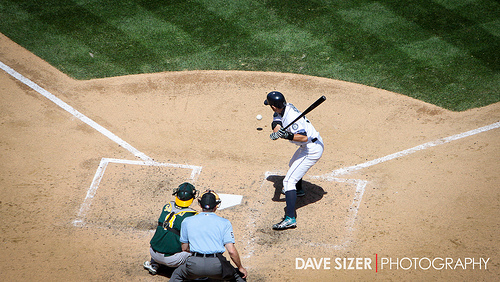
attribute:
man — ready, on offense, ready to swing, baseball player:
[264, 89, 327, 231]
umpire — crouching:
[168, 187, 249, 281]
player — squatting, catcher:
[143, 183, 199, 276]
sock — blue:
[285, 188, 299, 218]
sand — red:
[2, 30, 500, 281]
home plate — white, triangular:
[216, 193, 243, 213]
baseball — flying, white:
[256, 114, 263, 121]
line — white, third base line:
[0, 59, 152, 168]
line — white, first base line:
[319, 121, 499, 180]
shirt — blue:
[179, 210, 236, 254]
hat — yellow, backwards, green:
[175, 183, 195, 207]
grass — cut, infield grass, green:
[0, 0, 499, 112]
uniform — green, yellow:
[151, 200, 194, 266]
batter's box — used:
[73, 156, 368, 259]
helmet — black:
[263, 90, 286, 107]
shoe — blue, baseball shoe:
[272, 215, 298, 231]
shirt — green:
[151, 203, 192, 253]